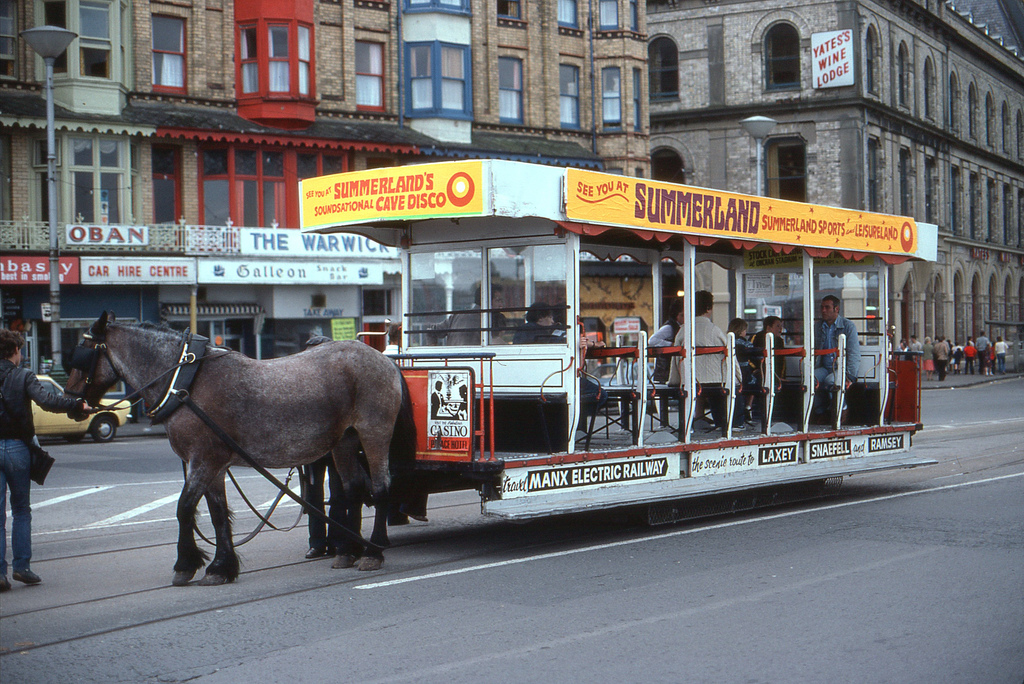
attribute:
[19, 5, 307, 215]
apartment building — large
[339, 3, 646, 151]
apartment buildings — large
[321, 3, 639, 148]
apartment building — large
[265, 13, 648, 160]
apartment building — large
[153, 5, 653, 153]
apartment building — large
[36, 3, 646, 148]
apartment building — large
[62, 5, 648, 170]
apartment building — large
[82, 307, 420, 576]
horse — brown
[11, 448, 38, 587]
jeans — blue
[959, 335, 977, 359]
shirt — red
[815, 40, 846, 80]
letters — red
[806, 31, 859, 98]
sign — white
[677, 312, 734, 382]
sweater — white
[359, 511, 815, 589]
line — white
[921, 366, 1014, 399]
curb — concrete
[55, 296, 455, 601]
horse — brown, with grey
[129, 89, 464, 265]
windows — red, group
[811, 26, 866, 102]
sign — that says Yates's Wine Lodge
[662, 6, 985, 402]
building — back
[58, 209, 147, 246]
sign — red, says Oban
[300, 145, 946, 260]
signs — yellow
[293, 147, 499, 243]
sign — yellow